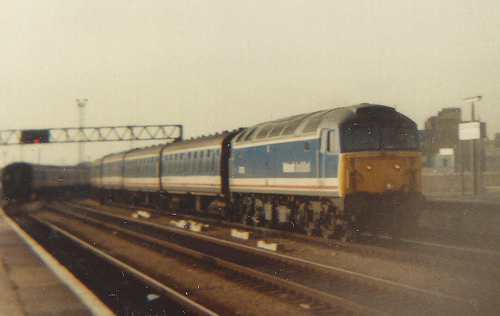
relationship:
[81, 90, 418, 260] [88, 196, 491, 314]
train on train tracks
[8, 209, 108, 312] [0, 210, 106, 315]
line at platform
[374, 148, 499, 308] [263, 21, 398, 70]
dirt blown into air